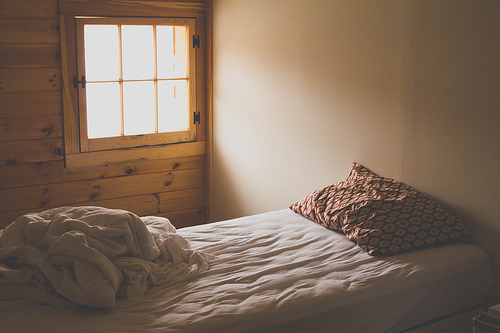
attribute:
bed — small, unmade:
[215, 253, 499, 332]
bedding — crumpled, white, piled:
[0, 204, 211, 313]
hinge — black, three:
[71, 73, 88, 92]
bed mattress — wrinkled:
[204, 221, 320, 317]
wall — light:
[210, 5, 293, 216]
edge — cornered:
[471, 303, 499, 333]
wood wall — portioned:
[0, 0, 65, 207]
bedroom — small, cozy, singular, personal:
[1, 0, 498, 331]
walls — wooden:
[1, 4, 213, 207]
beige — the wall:
[210, 4, 500, 160]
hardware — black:
[189, 33, 207, 126]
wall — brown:
[11, 33, 72, 189]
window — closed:
[76, 11, 202, 147]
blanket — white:
[38, 202, 186, 289]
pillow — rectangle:
[300, 160, 477, 260]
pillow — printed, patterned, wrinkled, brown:
[291, 157, 473, 255]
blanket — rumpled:
[16, 191, 201, 301]